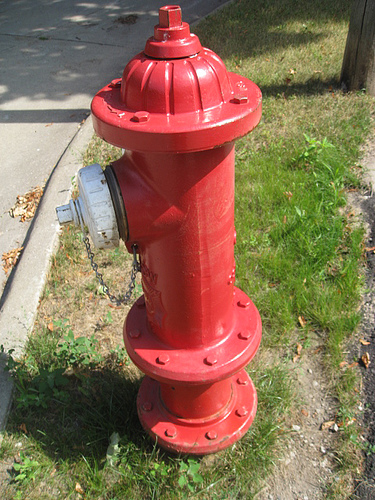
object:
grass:
[275, 144, 329, 232]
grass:
[253, 246, 298, 309]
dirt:
[262, 326, 333, 500]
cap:
[55, 161, 119, 252]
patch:
[260, 322, 344, 499]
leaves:
[9, 183, 43, 223]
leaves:
[361, 242, 375, 258]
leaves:
[337, 351, 374, 369]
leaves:
[293, 342, 303, 363]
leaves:
[297, 314, 307, 329]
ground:
[0, 0, 53, 117]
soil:
[305, 413, 320, 461]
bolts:
[134, 111, 150, 123]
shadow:
[0, 108, 94, 124]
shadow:
[0, 1, 350, 107]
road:
[0, 1, 92, 297]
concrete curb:
[0, 113, 94, 441]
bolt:
[157, 5, 182, 29]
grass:
[50, 371, 91, 456]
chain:
[82, 230, 141, 307]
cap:
[91, 5, 263, 155]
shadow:
[0, 346, 202, 472]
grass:
[270, 25, 325, 69]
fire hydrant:
[54, 4, 262, 456]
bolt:
[166, 426, 177, 437]